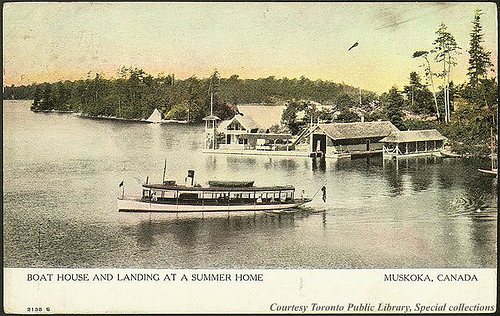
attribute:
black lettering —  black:
[5, 267, 495, 314]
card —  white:
[3, 2, 494, 310]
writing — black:
[381, 270, 479, 283]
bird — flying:
[342, 28, 359, 56]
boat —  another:
[473, 160, 498, 187]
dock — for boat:
[368, 117, 457, 164]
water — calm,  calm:
[2, 90, 495, 265]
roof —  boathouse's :
[320, 117, 404, 144]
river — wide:
[1, 100, 113, 230]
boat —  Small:
[438, 146, 471, 158]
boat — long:
[104, 163, 332, 227]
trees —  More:
[375, 10, 499, 146]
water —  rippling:
[329, 178, 485, 218]